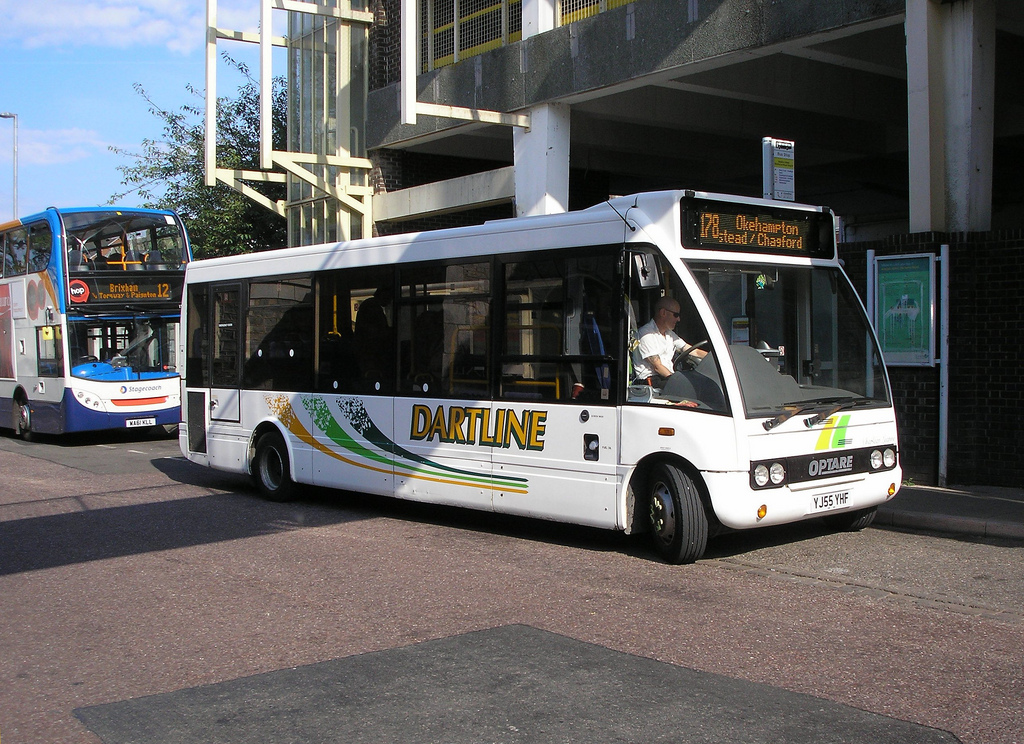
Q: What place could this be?
A: It is a street.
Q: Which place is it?
A: It is a street.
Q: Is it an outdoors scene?
A: Yes, it is outdoors.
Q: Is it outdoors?
A: Yes, it is outdoors.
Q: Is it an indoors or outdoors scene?
A: It is outdoors.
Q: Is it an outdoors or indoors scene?
A: It is outdoors.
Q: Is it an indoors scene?
A: No, it is outdoors.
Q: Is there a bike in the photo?
A: No, there are no bikes.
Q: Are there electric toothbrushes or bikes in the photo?
A: No, there are no bikes or electric toothbrushes.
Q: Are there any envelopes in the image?
A: No, there are no envelopes.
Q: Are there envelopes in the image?
A: No, there are no envelopes.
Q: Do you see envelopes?
A: No, there are no envelopes.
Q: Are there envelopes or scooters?
A: No, there are no envelopes or scooters.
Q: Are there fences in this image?
A: No, there are no fences.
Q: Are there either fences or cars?
A: No, there are no fences or cars.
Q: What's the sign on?
A: The sign is on the pole.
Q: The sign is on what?
A: The sign is on the pole.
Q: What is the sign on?
A: The sign is on the pole.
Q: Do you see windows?
A: Yes, there is a window.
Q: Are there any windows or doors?
A: Yes, there is a window.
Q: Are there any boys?
A: No, there are no boys.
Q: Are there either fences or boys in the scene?
A: No, there are no boys or fences.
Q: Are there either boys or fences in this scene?
A: No, there are no boys or fences.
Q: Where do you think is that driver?
A: The driver is in the bus.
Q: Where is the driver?
A: The driver is in the bus.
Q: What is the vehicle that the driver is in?
A: The vehicle is a bus.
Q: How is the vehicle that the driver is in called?
A: The vehicle is a bus.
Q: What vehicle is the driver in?
A: The driver is in the bus.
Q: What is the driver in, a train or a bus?
A: The driver is in a bus.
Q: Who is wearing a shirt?
A: The driver is wearing a shirt.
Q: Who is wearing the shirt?
A: The driver is wearing a shirt.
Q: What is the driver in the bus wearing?
A: The driver is wearing a shirt.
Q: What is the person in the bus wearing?
A: The driver is wearing a shirt.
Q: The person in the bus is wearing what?
A: The driver is wearing a shirt.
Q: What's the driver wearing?
A: The driver is wearing a shirt.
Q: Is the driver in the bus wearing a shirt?
A: Yes, the driver is wearing a shirt.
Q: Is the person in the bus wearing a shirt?
A: Yes, the driver is wearing a shirt.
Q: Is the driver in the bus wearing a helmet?
A: No, the driver is wearing a shirt.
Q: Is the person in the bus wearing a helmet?
A: No, the driver is wearing a shirt.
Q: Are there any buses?
A: Yes, there is a bus.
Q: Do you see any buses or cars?
A: Yes, there is a bus.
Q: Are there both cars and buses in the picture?
A: No, there is a bus but no cars.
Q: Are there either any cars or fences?
A: No, there are no cars or fences.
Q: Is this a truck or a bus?
A: This is a bus.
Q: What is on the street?
A: The bus is on the street.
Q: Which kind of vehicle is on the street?
A: The vehicle is a bus.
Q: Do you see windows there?
A: Yes, there is a window.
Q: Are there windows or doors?
A: Yes, there is a window.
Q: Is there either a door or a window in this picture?
A: Yes, there is a window.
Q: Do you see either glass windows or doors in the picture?
A: Yes, there is a glass window.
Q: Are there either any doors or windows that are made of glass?
A: Yes, the window is made of glass.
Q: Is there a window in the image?
A: Yes, there is a window.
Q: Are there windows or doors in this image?
A: Yes, there is a window.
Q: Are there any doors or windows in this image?
A: Yes, there is a window.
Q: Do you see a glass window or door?
A: Yes, there is a glass window.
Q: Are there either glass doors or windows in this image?
A: Yes, there is a glass window.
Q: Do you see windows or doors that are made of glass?
A: Yes, the window is made of glass.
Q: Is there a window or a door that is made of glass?
A: Yes, the window is made of glass.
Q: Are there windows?
A: Yes, there is a window.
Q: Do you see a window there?
A: Yes, there is a window.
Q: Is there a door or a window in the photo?
A: Yes, there is a window.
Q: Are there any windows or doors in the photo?
A: Yes, there is a window.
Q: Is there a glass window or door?
A: Yes, there is a glass window.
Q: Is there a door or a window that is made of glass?
A: Yes, the window is made of glass.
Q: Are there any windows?
A: Yes, there is a window.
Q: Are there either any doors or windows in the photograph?
A: Yes, there is a window.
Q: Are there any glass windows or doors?
A: Yes, there is a glass window.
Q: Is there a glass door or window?
A: Yes, there is a glass window.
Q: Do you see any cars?
A: No, there are no cars.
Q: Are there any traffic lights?
A: No, there are no traffic lights.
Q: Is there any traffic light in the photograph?
A: No, there are no traffic lights.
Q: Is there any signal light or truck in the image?
A: No, there are no traffic lights or trucks.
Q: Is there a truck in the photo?
A: No, there are no trucks.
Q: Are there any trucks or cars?
A: No, there are no trucks or cars.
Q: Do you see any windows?
A: Yes, there is a window.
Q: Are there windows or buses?
A: Yes, there is a window.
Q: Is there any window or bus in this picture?
A: Yes, there is a window.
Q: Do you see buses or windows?
A: Yes, there is a window.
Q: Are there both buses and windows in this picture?
A: Yes, there are both a window and a bus.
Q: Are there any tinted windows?
A: Yes, there is a tinted window.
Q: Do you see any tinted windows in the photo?
A: Yes, there is a tinted window.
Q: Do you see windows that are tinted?
A: Yes, there is a window that is tinted.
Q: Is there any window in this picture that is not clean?
A: Yes, there is a tinted window.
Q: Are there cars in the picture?
A: No, there are no cars.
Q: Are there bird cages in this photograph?
A: No, there are no bird cages.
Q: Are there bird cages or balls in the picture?
A: No, there are no bird cages or balls.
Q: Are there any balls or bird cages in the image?
A: No, there are no bird cages or balls.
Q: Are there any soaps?
A: No, there are no soaps.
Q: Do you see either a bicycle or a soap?
A: No, there are no soaps or bicycles.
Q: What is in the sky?
A: The clouds are in the sky.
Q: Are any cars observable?
A: No, there are no cars.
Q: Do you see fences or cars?
A: No, there are no cars or fences.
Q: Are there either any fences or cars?
A: No, there are no cars or fences.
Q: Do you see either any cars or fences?
A: No, there are no cars or fences.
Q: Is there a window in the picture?
A: Yes, there is a window.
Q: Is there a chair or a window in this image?
A: Yes, there is a window.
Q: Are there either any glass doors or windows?
A: Yes, there is a glass window.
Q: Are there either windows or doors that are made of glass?
A: Yes, the window is made of glass.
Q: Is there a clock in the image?
A: No, there are no clocks.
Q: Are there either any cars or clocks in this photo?
A: No, there are no clocks or cars.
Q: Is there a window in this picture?
A: Yes, there is a window.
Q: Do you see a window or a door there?
A: Yes, there is a window.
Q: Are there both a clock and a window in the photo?
A: No, there is a window but no clocks.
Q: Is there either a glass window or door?
A: Yes, there is a glass window.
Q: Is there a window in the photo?
A: Yes, there is a window.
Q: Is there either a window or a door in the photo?
A: Yes, there is a window.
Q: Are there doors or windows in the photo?
A: Yes, there is a window.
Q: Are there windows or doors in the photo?
A: Yes, there is a window.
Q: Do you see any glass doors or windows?
A: Yes, there is a glass window.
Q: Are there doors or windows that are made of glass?
A: Yes, the window is made of glass.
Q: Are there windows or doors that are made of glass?
A: Yes, the window is made of glass.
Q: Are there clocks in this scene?
A: No, there are no clocks.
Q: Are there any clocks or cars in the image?
A: No, there are no clocks or cars.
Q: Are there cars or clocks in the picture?
A: No, there are no clocks or cars.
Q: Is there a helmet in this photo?
A: No, there are no helmets.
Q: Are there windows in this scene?
A: Yes, there is a window.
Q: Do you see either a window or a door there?
A: Yes, there is a window.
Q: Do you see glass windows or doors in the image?
A: Yes, there is a glass window.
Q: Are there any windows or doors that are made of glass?
A: Yes, the window is made of glass.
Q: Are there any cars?
A: No, there are no cars.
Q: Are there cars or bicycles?
A: No, there are no cars or bicycles.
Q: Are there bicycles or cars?
A: No, there are no cars or bicycles.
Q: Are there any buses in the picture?
A: Yes, there is a bus.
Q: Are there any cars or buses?
A: Yes, there is a bus.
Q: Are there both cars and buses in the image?
A: No, there is a bus but no cars.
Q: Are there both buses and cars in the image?
A: No, there is a bus but no cars.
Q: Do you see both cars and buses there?
A: No, there is a bus but no cars.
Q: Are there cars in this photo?
A: No, there are no cars.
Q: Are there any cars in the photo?
A: No, there are no cars.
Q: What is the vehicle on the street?
A: The vehicle is a bus.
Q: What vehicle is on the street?
A: The vehicle is a bus.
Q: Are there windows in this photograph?
A: Yes, there is a window.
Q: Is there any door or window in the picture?
A: Yes, there is a window.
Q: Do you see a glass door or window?
A: Yes, there is a glass window.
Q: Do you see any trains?
A: No, there are no trains.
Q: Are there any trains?
A: No, there are no trains.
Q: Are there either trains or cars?
A: No, there are no trains or cars.